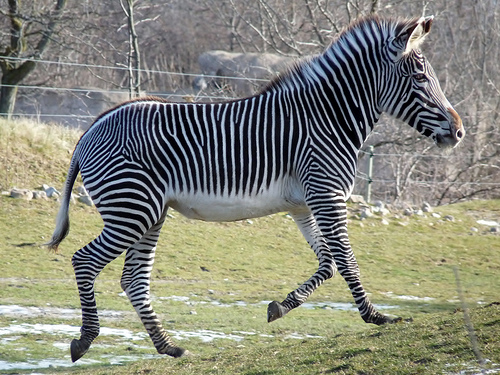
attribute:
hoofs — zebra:
[64, 337, 190, 364]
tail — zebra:
[41, 160, 81, 248]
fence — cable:
[368, 130, 499, 222]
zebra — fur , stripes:
[42, 5, 475, 370]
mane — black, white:
[255, 13, 422, 95]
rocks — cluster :
[420, 200, 430, 210]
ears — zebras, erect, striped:
[396, 2, 435, 64]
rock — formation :
[34, 69, 108, 117]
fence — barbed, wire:
[16, 45, 481, 217]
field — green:
[0, 116, 497, 373]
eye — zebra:
[414, 71, 426, 83]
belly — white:
[164, 180, 293, 224]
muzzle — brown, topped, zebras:
[432, 100, 469, 153]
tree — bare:
[1, 1, 83, 122]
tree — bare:
[109, 3, 159, 102]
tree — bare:
[203, 1, 255, 49]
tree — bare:
[251, 1, 277, 51]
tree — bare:
[461, 1, 483, 196]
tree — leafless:
[129, 0, 144, 99]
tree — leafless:
[120, 5, 159, 101]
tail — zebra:
[45, 150, 81, 251]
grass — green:
[2, 117, 499, 373]